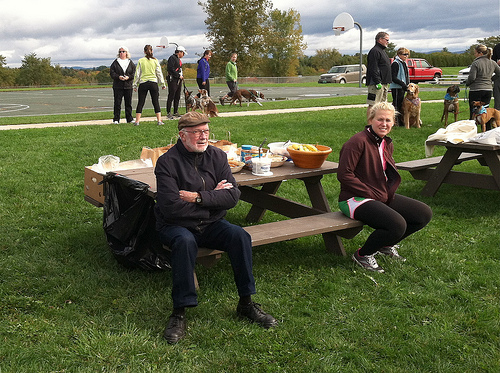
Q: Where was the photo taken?
A: At a park.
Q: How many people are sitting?
A: Two.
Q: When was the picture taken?
A: Daytime.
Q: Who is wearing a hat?
A: Man sitting down.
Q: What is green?
A: Grass.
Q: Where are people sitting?
A: On a picnic bench.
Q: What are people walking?
A: Dogs.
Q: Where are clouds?
A: In the sky.